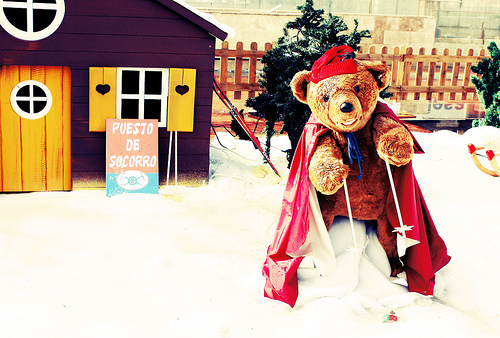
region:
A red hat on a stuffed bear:
[306, 46, 360, 81]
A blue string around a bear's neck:
[342, 127, 365, 178]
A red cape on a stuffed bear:
[257, 110, 448, 302]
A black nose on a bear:
[337, 102, 351, 112]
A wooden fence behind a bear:
[221, 38, 479, 95]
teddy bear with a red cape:
[258, 45, 448, 303]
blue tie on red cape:
[345, 133, 363, 178]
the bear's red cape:
[269, 104, 449, 304]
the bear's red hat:
[307, 45, 357, 78]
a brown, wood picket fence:
[215, 41, 489, 102]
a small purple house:
[2, 0, 223, 194]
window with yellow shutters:
[90, 67, 193, 132]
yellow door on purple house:
[1, 68, 71, 190]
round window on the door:
[12, 83, 49, 118]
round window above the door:
[0, 1, 65, 41]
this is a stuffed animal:
[213, 6, 448, 313]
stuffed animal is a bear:
[257, 20, 439, 322]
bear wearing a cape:
[252, 35, 447, 306]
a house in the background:
[5, 5, 237, 207]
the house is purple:
[5, 3, 251, 226]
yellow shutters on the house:
[83, 60, 205, 135]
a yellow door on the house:
[6, 46, 68, 201]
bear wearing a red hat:
[286, 34, 410, 147]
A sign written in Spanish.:
[102, 117, 158, 197]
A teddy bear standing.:
[262, 43, 447, 302]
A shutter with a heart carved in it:
[166, 69, 198, 131]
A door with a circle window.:
[2, 61, 77, 195]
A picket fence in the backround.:
[384, 45, 469, 101]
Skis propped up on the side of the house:
[208, 73, 281, 179]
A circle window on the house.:
[1, 0, 76, 42]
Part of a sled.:
[465, 136, 499, 180]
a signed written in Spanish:
[99, 106, 167, 198]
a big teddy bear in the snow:
[260, 29, 462, 316]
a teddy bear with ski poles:
[279, 39, 454, 317]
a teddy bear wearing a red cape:
[264, 29, 461, 323]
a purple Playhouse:
[9, 0, 229, 216]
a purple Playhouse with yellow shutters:
[9, 11, 218, 197]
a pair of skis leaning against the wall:
[197, 46, 279, 186]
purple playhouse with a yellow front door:
[10, 4, 214, 191]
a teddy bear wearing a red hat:
[284, 34, 403, 141]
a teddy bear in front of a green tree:
[256, 2, 415, 174]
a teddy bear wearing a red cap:
[250, 31, 463, 317]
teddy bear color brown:
[281, 42, 425, 280]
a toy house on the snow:
[1, 1, 234, 204]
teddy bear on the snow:
[247, 42, 462, 319]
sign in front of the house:
[96, 111, 170, 203]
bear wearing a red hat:
[309, 44, 366, 82]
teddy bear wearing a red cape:
[244, 97, 451, 306]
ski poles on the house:
[206, 75, 289, 185]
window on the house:
[114, 64, 170, 124]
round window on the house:
[13, 84, 48, 114]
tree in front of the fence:
[256, 5, 379, 145]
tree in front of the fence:
[456, 33, 499, 120]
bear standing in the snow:
[243, 61, 449, 329]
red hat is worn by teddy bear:
[308, 43, 367, 83]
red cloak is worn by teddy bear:
[264, 96, 453, 307]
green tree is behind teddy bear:
[249, 0, 371, 172]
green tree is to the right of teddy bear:
[469, 40, 499, 129]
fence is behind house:
[212, 31, 497, 108]